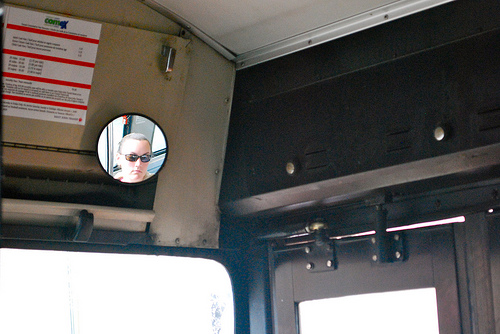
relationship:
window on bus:
[26, 252, 158, 324] [0, 7, 499, 334]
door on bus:
[270, 215, 487, 334] [0, 7, 499, 334]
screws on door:
[423, 116, 469, 146] [270, 215, 487, 334]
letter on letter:
[3, 3, 101, 125] [3, 3, 101, 125]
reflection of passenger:
[82, 110, 185, 188] [125, 128, 159, 175]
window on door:
[26, 252, 158, 324] [270, 215, 487, 334]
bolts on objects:
[303, 236, 404, 286] [259, 193, 443, 297]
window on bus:
[26, 252, 158, 324] [10, 7, 457, 274]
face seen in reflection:
[118, 126, 157, 162] [97, 115, 168, 184]